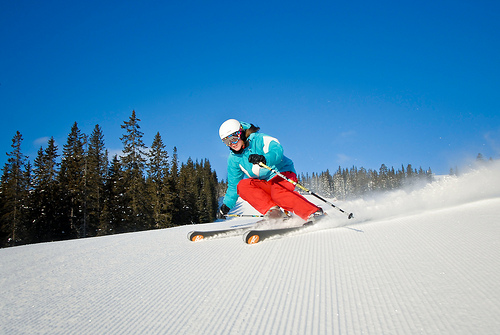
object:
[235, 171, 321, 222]
pants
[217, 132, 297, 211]
coat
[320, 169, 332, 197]
pine trees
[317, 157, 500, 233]
snow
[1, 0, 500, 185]
sky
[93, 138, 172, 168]
clouds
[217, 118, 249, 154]
head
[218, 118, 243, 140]
helmet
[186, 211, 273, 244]
ski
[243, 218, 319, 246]
ski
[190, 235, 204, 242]
circle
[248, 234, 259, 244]
circle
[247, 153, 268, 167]
glove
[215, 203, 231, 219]
glove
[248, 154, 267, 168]
hand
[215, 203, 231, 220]
hand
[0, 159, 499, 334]
snow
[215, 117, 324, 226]
girl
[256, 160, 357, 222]
ski pole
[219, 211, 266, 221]
ski pole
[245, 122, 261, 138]
hair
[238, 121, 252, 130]
hair tie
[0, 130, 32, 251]
evergreen trees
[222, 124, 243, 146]
snow goggles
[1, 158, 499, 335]
hill